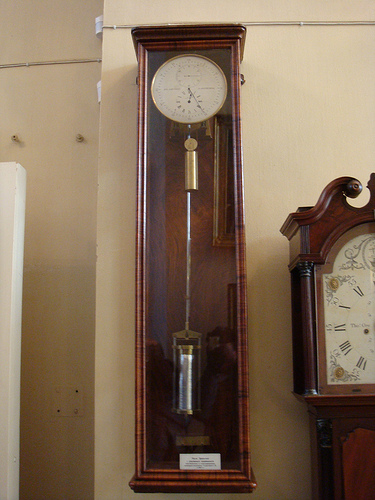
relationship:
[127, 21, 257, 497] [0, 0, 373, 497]
brown clock hangs on wall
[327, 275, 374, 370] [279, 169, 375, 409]
numerals on clock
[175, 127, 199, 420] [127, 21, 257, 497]
chime hanging from brown clock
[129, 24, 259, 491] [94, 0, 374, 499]
brown clock hanging on wall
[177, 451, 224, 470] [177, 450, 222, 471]
white card with black writing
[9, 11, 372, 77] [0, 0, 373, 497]
pipe secured to wall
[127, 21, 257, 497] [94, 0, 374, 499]
brown clock on wall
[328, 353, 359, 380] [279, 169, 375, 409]
design on clock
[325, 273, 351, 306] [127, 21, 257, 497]
design on brown clock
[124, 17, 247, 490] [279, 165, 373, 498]
clock in case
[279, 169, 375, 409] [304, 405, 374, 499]
clock on stand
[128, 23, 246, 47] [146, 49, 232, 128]
trim on clock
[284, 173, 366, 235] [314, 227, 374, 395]
trim on clock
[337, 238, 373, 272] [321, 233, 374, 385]
design on clock face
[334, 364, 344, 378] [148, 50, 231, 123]
mark on clock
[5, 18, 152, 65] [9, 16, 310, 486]
cord along wall